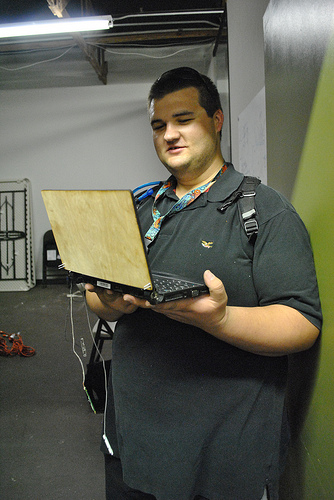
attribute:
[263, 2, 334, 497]
wall — green